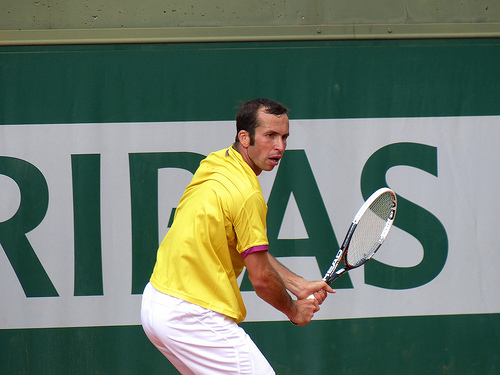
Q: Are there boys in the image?
A: No, there are no boys.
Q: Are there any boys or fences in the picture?
A: No, there are no boys or fences.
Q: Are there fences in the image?
A: No, there are no fences.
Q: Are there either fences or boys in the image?
A: No, there are no fences or boys.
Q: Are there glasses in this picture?
A: No, there are no glasses.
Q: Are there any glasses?
A: No, there are no glasses.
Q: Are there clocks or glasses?
A: No, there are no glasses or clocks.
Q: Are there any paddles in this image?
A: No, there are no paddles.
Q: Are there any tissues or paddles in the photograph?
A: No, there are no paddles or tissues.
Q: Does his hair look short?
A: Yes, the hair is short.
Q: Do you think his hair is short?
A: Yes, the hair is short.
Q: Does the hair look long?
A: No, the hair is short.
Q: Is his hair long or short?
A: The hair is short.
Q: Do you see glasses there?
A: No, there are no glasses.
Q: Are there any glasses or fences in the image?
A: No, there are no glasses or fences.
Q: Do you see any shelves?
A: No, there are no shelves.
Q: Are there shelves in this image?
A: No, there are no shelves.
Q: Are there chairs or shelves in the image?
A: No, there are no shelves or chairs.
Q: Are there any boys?
A: No, there are no boys.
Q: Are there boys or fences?
A: No, there are no boys or fences.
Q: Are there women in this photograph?
A: No, there are no women.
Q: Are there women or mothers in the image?
A: No, there are no women or mothers.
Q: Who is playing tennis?
A: The man is playing tennis.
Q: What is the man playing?
A: The man is playing tennis.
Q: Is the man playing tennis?
A: Yes, the man is playing tennis.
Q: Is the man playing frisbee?
A: No, the man is playing tennis.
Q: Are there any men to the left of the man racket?
A: Yes, there is a man to the left of the racket.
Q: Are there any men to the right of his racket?
A: No, the man is to the left of the tennis racket.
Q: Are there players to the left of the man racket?
A: No, there is a man to the left of the tennis racket.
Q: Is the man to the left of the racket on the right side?
A: Yes, the man is to the left of the tennis racket.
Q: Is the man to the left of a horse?
A: No, the man is to the left of the tennis racket.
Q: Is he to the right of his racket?
A: No, the man is to the left of the racket.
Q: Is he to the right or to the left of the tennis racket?
A: The man is to the left of the tennis racket.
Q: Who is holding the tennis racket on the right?
A: The man is holding the tennis racket.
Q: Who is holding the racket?
A: The man is holding the tennis racket.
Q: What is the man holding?
A: The man is holding the racket.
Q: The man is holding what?
A: The man is holding the racket.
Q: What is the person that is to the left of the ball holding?
A: The man is holding the racket.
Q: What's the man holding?
A: The man is holding the racket.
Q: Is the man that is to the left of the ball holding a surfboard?
A: No, the man is holding the racket.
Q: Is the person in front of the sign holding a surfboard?
A: No, the man is holding the racket.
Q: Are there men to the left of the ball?
A: Yes, there is a man to the left of the ball.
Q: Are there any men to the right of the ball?
A: No, the man is to the left of the ball.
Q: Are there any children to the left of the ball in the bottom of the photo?
A: No, there is a man to the left of the ball.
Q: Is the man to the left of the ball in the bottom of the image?
A: Yes, the man is to the left of the ball.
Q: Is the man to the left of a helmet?
A: No, the man is to the left of the ball.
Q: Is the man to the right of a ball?
A: No, the man is to the left of a ball.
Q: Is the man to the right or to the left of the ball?
A: The man is to the left of the ball.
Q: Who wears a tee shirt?
A: The man wears a tee shirt.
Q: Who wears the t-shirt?
A: The man wears a tee shirt.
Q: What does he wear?
A: The man wears a tee shirt.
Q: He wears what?
A: The man wears a tee shirt.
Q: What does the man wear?
A: The man wears a tee shirt.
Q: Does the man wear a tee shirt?
A: Yes, the man wears a tee shirt.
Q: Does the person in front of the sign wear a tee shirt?
A: Yes, the man wears a tee shirt.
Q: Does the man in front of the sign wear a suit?
A: No, the man wears a tee shirt.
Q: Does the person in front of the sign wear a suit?
A: No, the man wears a tee shirt.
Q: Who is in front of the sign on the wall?
A: The man is in front of the sign.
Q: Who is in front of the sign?
A: The man is in front of the sign.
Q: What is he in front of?
A: The man is in front of the sign.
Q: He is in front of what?
A: The man is in front of the sign.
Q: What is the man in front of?
A: The man is in front of the sign.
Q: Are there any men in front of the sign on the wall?
A: Yes, there is a man in front of the sign.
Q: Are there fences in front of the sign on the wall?
A: No, there is a man in front of the sign.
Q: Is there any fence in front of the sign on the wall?
A: No, there is a man in front of the sign.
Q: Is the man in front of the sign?
A: Yes, the man is in front of the sign.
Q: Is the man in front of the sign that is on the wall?
A: Yes, the man is in front of the sign.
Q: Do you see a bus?
A: No, there are no buses.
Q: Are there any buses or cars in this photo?
A: No, there are no buses or cars.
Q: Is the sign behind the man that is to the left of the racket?
A: Yes, the sign is behind the man.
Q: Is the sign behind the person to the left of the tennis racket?
A: Yes, the sign is behind the man.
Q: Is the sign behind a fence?
A: No, the sign is behind the man.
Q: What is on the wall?
A: The sign is on the wall.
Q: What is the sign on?
A: The sign is on the wall.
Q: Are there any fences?
A: No, there are no fences.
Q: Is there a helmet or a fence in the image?
A: No, there are no fences or helmets.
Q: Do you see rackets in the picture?
A: Yes, there is a racket.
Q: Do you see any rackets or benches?
A: Yes, there is a racket.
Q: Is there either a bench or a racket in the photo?
A: Yes, there is a racket.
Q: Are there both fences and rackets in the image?
A: No, there is a racket but no fences.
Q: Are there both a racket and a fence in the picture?
A: No, there is a racket but no fences.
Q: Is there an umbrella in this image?
A: No, there are no umbrellas.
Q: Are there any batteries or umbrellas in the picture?
A: No, there are no umbrellas or batteries.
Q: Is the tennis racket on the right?
A: Yes, the tennis racket is on the right of the image.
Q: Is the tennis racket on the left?
A: No, the tennis racket is on the right of the image.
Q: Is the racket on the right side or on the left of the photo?
A: The racket is on the right of the image.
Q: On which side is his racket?
A: The racket is on the right of the image.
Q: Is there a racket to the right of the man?
A: Yes, there is a racket to the right of the man.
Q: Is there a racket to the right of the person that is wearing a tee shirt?
A: Yes, there is a racket to the right of the man.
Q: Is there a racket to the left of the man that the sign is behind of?
A: No, the racket is to the right of the man.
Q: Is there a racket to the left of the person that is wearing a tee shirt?
A: No, the racket is to the right of the man.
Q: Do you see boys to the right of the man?
A: No, there is a racket to the right of the man.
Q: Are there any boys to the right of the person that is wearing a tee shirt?
A: No, there is a racket to the right of the man.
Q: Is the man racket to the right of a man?
A: Yes, the tennis racket is to the right of a man.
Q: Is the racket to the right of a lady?
A: No, the racket is to the right of a man.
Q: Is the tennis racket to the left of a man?
A: No, the tennis racket is to the right of a man.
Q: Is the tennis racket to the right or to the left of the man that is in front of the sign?
A: The tennis racket is to the right of the man.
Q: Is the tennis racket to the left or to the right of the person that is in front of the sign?
A: The tennis racket is to the right of the man.